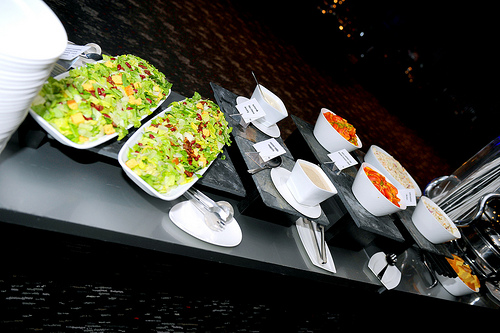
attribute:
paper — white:
[326, 144, 357, 178]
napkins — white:
[305, 216, 335, 273]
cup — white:
[278, 155, 341, 215]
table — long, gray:
[6, 15, 499, 326]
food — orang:
[361, 165, 403, 208]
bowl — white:
[311, 104, 363, 158]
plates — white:
[0, 1, 67, 161]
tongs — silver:
[185, 186, 240, 232]